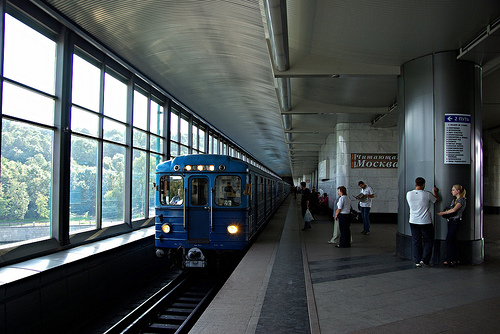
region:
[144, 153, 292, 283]
this is a train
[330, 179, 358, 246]
this is a person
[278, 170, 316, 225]
this is a person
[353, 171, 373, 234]
this is a person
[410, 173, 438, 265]
this is a person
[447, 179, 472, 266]
this is a person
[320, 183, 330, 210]
this is a person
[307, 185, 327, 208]
this is a person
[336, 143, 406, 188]
writing on a wall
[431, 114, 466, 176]
writing on a wall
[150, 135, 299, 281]
blue train parked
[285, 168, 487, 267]
people standing at train station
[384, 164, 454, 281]
man wearing white shirt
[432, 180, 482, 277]
lady standing against pillar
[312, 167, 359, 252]
people waiting for train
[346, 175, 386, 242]
man reading paper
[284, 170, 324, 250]
man standing at train station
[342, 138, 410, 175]
sign on the wall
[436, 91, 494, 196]
sign on the pillar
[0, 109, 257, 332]
rail way tracks for train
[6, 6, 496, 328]
a train pulling in to an indoor area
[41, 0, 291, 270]
area of ceiling above train is curved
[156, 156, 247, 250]
front lights of train are illuminated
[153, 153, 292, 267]
train is royal blue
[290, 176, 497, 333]
people on the platform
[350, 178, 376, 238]
man reading from object in his hands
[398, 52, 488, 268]
man's hand on very large pillar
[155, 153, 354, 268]
woman looking towards train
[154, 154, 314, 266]
man standing near train is holding a white bag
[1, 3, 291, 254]
view of scenery outside through windows to the left of train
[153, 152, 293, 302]
The blue train on tracks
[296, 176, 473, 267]
People waiting next to the tracks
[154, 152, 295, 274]
The lightened train headlights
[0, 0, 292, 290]
The long clear glass windows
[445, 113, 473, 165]
A wall sign in the tunnel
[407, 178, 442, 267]
The man touching the wall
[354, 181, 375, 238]
The man reading a newsprint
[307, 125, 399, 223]
The white marked tunnels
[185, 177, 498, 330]
A long tiled hallway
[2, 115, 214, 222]
Bushes outside the train's tunnel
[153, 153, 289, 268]
Blue train arriving on tracks at station.